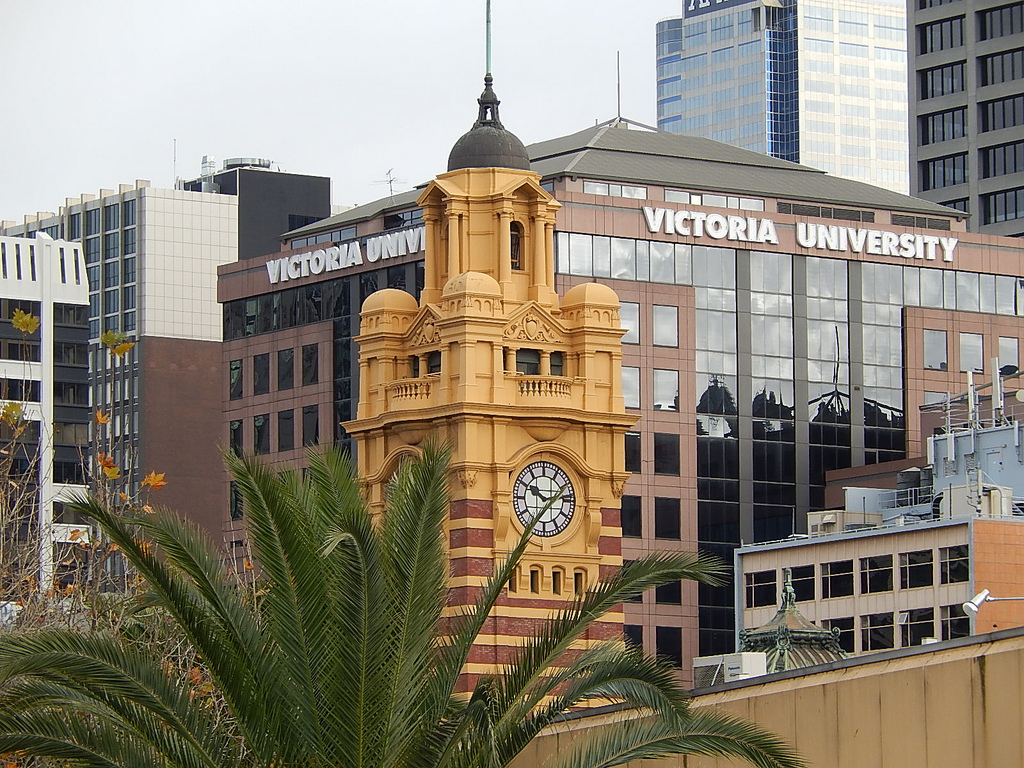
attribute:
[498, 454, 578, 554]
clock — large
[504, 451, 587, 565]
clock — large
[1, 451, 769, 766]
tree — palm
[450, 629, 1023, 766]
building — small